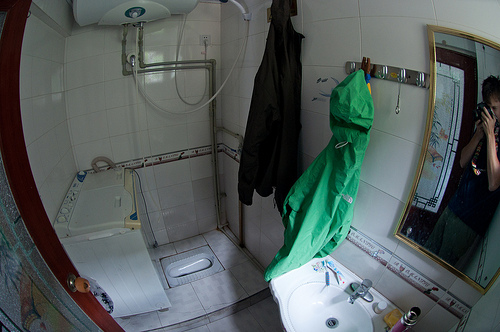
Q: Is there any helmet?
A: No, there are no helmets.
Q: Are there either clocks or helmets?
A: No, there are no helmets or clocks.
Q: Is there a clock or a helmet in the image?
A: No, there are no helmets or clocks.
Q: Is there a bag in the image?
A: No, there are no bags.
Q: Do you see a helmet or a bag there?
A: No, there are no bags or helmets.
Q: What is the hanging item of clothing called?
A: The clothing item is a jacket.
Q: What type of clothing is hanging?
A: The clothing is a jacket.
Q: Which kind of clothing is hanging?
A: The clothing is a jacket.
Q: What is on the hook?
A: The jacket is on the hook.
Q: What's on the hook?
A: The jacket is on the hook.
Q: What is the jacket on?
A: The jacket is on the hook.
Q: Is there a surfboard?
A: No, there are no surfboards.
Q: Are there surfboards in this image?
A: No, there are no surfboards.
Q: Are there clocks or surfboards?
A: No, there are no surfboards or clocks.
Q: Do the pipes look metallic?
A: Yes, the pipes are metallic.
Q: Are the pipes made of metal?
A: Yes, the pipes are made of metal.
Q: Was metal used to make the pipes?
A: Yes, the pipes are made of metal.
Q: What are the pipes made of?
A: The pipes are made of metal.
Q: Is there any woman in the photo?
A: No, there are no women.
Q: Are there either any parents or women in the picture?
A: No, there are no women or parents.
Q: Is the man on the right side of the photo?
A: Yes, the man is on the right of the image.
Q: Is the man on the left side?
A: No, the man is on the right of the image.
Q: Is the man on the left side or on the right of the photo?
A: The man is on the right of the image.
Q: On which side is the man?
A: The man is on the right of the image.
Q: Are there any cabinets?
A: No, there are no cabinets.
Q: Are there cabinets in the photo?
A: No, there are no cabinets.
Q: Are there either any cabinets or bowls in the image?
A: No, there are no cabinets or bowls.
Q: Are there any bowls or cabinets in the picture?
A: No, there are no cabinets or bowls.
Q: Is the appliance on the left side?
A: Yes, the appliance is on the left of the image.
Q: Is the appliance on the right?
A: No, the appliance is on the left of the image.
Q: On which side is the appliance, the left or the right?
A: The appliance is on the left of the image.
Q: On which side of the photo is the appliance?
A: The appliance is on the left of the image.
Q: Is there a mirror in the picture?
A: Yes, there is a mirror.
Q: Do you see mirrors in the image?
A: Yes, there is a mirror.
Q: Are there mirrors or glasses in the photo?
A: Yes, there is a mirror.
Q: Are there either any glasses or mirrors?
A: Yes, there is a mirror.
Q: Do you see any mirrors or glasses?
A: Yes, there is a mirror.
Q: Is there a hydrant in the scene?
A: No, there are no fire hydrants.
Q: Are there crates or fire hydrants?
A: No, there are no fire hydrants or crates.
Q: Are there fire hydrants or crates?
A: No, there are no fire hydrants or crates.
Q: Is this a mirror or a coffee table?
A: This is a mirror.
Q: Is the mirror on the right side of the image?
A: Yes, the mirror is on the right of the image.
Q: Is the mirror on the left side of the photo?
A: No, the mirror is on the right of the image.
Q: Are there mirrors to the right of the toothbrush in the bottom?
A: Yes, there is a mirror to the right of the toothbrush.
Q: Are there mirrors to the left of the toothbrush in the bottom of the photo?
A: No, the mirror is to the right of the toothbrush.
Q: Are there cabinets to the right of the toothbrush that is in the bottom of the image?
A: No, there is a mirror to the right of the toothbrush.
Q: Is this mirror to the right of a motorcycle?
A: No, the mirror is to the right of a toothbrush.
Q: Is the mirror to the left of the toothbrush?
A: No, the mirror is to the right of the toothbrush.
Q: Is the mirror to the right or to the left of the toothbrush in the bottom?
A: The mirror is to the right of the toothbrush.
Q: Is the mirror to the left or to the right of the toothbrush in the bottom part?
A: The mirror is to the right of the toothbrush.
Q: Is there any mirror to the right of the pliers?
A: Yes, there is a mirror to the right of the pliers.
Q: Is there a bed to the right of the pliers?
A: No, there is a mirror to the right of the pliers.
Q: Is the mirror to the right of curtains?
A: No, the mirror is to the right of the pliers.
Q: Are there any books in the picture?
A: No, there are no books.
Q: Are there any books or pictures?
A: No, there are no books or pictures.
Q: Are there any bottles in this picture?
A: Yes, there is a bottle.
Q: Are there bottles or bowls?
A: Yes, there is a bottle.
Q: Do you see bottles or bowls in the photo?
A: Yes, there is a bottle.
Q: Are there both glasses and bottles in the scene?
A: No, there is a bottle but no glasses.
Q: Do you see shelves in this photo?
A: No, there are no shelves.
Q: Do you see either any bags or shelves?
A: No, there are no shelves or bags.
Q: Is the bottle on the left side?
A: No, the bottle is on the right of the image.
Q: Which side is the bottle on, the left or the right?
A: The bottle is on the right of the image.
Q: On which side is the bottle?
A: The bottle is on the right of the image.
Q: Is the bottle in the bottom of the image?
A: Yes, the bottle is in the bottom of the image.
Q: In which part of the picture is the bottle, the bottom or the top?
A: The bottle is in the bottom of the image.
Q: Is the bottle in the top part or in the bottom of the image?
A: The bottle is in the bottom of the image.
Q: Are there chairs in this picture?
A: No, there are no chairs.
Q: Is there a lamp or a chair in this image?
A: No, there are no chairs or lamps.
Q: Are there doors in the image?
A: Yes, there is a door.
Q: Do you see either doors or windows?
A: Yes, there is a door.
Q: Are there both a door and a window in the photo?
A: No, there is a door but no windows.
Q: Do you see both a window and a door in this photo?
A: No, there is a door but no windows.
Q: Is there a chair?
A: No, there are no chairs.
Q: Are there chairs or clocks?
A: No, there are no chairs or clocks.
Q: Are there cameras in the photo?
A: Yes, there is a camera.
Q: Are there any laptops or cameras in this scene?
A: Yes, there is a camera.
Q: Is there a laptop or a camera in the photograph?
A: Yes, there is a camera.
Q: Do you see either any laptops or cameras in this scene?
A: Yes, there is a camera.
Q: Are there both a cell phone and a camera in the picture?
A: No, there is a camera but no cell phones.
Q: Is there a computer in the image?
A: No, there are no computers.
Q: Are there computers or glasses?
A: No, there are no computers or glasses.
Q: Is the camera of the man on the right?
A: Yes, the camera is on the right of the image.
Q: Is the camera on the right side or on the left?
A: The camera is on the right of the image.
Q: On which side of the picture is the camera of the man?
A: The camera is on the right of the image.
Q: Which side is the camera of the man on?
A: The camera is on the right of the image.